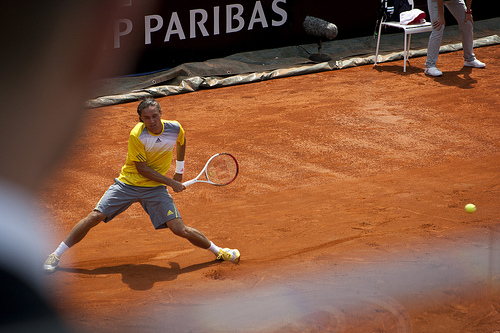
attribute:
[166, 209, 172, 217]
logo — adidas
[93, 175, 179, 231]
shorts — grey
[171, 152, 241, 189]
tennisracket — white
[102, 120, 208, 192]
shirt — yellow, gray, white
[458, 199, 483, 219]
ball — sailing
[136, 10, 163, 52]
letter — white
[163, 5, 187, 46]
letter — white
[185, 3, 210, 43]
letter — white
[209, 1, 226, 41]
letter — white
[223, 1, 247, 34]
letter — white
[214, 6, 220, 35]
letter — white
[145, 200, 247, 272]
leg — man's, spread apart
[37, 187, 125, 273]
leg — spread apart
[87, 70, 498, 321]
court — brown, clay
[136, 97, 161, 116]
hair — blonde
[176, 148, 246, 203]
racquet — red, white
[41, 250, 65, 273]
sneakers — white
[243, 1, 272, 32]
letter — white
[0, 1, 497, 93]
wall — courtside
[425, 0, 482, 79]
pants — gray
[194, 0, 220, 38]
letter — white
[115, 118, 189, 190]
shirt — yellow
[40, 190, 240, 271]
legs — stretched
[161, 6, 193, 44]
letter — white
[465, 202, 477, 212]
ball — in flight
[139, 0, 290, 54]
part name — French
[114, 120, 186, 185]
shirt — yellow, gray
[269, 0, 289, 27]
letter — white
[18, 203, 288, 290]
sneakers — white, yellow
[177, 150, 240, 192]
racket — tennis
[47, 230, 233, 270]
socks — white